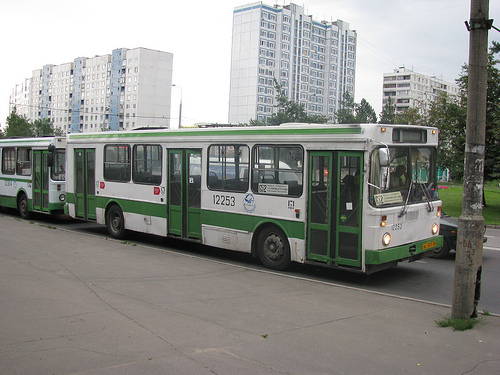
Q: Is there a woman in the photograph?
A: No, there are no women.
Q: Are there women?
A: No, there are no women.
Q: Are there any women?
A: No, there are no women.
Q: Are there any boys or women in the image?
A: No, there are no women or boys.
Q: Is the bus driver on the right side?
A: Yes, the bus driver is on the right of the image.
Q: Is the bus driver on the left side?
A: No, the bus driver is on the right of the image.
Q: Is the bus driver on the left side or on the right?
A: The bus driver is on the right of the image.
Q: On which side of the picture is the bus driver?
A: The bus driver is on the right of the image.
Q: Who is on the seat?
A: The bus driver is on the seat.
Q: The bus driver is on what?
A: The bus driver is on the seat.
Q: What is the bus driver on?
A: The bus driver is on the seat.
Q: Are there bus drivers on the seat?
A: Yes, there is a bus driver on the seat.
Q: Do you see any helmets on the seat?
A: No, there is a bus driver on the seat.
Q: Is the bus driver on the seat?
A: Yes, the bus driver is on the seat.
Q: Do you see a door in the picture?
A: Yes, there are doors.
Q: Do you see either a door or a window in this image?
A: Yes, there are doors.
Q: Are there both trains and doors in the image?
A: No, there are doors but no trains.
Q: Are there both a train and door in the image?
A: No, there are doors but no trains.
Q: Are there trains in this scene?
A: No, there are no trains.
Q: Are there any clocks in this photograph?
A: No, there are no clocks.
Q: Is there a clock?
A: No, there are no clocks.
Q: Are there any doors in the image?
A: Yes, there is a door.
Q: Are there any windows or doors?
A: Yes, there is a door.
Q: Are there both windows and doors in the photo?
A: Yes, there are both a door and a window.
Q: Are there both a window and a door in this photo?
A: Yes, there are both a door and a window.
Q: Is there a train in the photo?
A: No, there are no trains.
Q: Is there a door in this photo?
A: Yes, there is a door.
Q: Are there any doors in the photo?
A: Yes, there is a door.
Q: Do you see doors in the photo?
A: Yes, there is a door.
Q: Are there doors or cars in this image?
A: Yes, there is a door.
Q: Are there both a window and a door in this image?
A: Yes, there are both a door and a window.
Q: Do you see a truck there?
A: No, there are no trucks.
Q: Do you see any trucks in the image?
A: No, there are no trucks.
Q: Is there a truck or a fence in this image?
A: No, there are no trucks or fences.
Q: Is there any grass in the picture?
A: Yes, there is grass.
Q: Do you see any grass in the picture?
A: Yes, there is grass.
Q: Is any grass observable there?
A: Yes, there is grass.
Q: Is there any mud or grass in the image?
A: Yes, there is grass.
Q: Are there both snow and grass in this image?
A: No, there is grass but no snow.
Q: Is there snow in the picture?
A: No, there is no snow.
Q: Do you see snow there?
A: No, there is no snow.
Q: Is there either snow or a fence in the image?
A: No, there are no snow or fences.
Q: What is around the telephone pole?
A: The grass is around the telephone pole.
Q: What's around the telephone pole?
A: The grass is around the telephone pole.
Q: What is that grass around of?
A: The grass is around the utility pole.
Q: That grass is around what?
A: The grass is around the utility pole.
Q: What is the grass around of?
A: The grass is around the utility pole.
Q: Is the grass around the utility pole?
A: Yes, the grass is around the utility pole.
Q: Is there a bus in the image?
A: Yes, there is a bus.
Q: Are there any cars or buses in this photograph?
A: Yes, there is a bus.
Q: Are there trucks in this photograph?
A: No, there are no trucks.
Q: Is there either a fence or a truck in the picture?
A: No, there are no trucks or fences.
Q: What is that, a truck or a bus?
A: That is a bus.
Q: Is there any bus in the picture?
A: Yes, there is a bus.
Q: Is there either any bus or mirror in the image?
A: Yes, there is a bus.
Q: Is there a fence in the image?
A: No, there are no fences.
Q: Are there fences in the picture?
A: No, there are no fences.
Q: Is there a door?
A: Yes, there is a door.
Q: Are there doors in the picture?
A: Yes, there is a door.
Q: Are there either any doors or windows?
A: Yes, there is a door.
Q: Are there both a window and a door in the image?
A: Yes, there are both a door and a window.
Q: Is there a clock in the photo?
A: No, there are no clocks.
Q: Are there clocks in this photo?
A: No, there are no clocks.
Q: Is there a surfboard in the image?
A: No, there are no surfboards.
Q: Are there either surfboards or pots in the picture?
A: No, there are no surfboards or pots.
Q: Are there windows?
A: Yes, there is a window.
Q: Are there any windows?
A: Yes, there is a window.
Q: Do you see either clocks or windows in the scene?
A: Yes, there is a window.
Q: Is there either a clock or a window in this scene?
A: Yes, there is a window.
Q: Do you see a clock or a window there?
A: Yes, there is a window.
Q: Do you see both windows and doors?
A: Yes, there are both a window and a door.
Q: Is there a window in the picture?
A: Yes, there is a window.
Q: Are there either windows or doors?
A: Yes, there is a window.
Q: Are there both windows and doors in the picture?
A: Yes, there are both a window and a door.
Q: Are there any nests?
A: No, there are no nests.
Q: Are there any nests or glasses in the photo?
A: No, there are no nests or glasses.